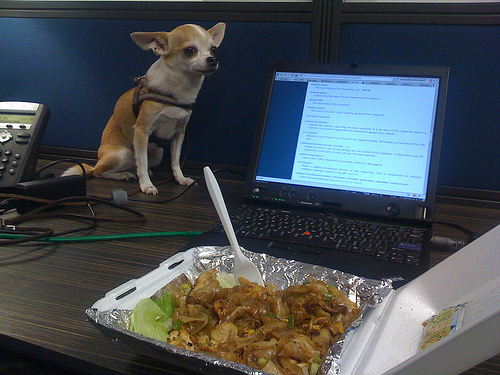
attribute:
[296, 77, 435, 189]
image — glowing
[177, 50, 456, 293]
laptop — black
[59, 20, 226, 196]
dog — brown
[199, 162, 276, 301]
utensil — white , standing up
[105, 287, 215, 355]
lettuce — green 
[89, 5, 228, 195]
dog — little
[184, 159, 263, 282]
fork — plastic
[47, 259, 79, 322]
table — wooden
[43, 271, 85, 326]
table — wooden